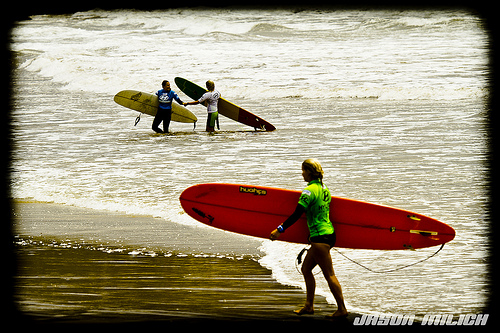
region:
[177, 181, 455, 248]
the long red surfboard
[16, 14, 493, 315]
the large body of water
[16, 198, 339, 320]
the wet sand near the water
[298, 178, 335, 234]
the green shirt on the woman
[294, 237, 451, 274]
the chord on the surfboard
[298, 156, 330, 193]
the blond hair on the woman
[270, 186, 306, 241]
the woman's left arm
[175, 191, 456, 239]
the line going down the red surfboard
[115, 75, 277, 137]
two people carrying their surfboards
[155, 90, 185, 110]
the blue top on the woman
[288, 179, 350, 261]
girls lime green surf shirt with advertising print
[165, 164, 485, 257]
long red surf board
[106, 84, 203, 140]
long yellow surf board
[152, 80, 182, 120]
long sleeve blue shirt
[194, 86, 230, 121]
long sleeve white shirt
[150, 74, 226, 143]
two people shaking hand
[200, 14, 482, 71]
white caps on top of waves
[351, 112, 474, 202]
white bubbles on water coming in to shore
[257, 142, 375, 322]
girl carrying a red board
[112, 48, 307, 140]
two people carrying surfboards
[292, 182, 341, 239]
Green shirt on woman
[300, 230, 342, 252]
Black bottoms on woman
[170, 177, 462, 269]
Red surfboard in woman's hand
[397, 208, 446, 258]
Fins on bottom of surfboard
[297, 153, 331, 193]
Blonde hair of woman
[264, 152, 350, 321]
Woman holding red surfboard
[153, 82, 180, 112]
Blue shirt on person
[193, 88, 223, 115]
White shirt on person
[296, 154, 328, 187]
Head of woman surfer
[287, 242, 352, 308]
Legs of woman surfer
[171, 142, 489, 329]
a surfer carrying her surfboard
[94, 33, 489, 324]
three surfers walking to shore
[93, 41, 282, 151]
two surfers shaking hands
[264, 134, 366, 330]
a surfer wearing a neon green rashguard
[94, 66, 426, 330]
people walking through shallow water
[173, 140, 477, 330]
a girl carrying her longboard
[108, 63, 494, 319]
three longboard surfers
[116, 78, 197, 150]
a man in a black and blue wetsuit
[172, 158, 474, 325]
a girl walking to shore after surfing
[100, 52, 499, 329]
three people enjoying the beach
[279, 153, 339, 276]
Girl wearing green shirt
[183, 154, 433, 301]
Girl carrying a red surfboard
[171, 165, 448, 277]
Red surfboard with yellow stickers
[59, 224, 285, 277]
Shoreline of the ocean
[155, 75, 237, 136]
Two people shaking hands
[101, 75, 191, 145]
Person wearing a blue shirt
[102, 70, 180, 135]
Person carrying a yellow surfboard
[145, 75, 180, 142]
Person wearing black pants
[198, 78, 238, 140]
Person wearing lime green shorts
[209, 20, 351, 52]
Small waves in the ocean